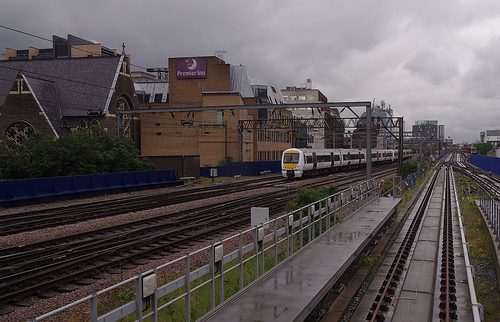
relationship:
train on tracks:
[275, 143, 416, 183] [3, 152, 398, 321]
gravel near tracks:
[2, 172, 278, 251] [3, 152, 398, 321]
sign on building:
[173, 56, 210, 81] [137, 56, 309, 179]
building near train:
[137, 56, 309, 179] [275, 143, 416, 183]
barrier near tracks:
[3, 166, 180, 204] [3, 152, 398, 321]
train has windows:
[275, 143, 416, 183] [304, 153, 341, 164]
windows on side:
[304, 153, 341, 164] [300, 149, 393, 175]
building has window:
[0, 50, 131, 156] [3, 120, 39, 161]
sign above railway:
[173, 56, 210, 81] [3, 152, 398, 321]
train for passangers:
[275, 143, 416, 183] [279, 147, 410, 180]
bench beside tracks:
[183, 194, 405, 321] [3, 152, 398, 321]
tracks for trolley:
[361, 150, 495, 316] [454, 143, 478, 159]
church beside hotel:
[0, 50, 131, 156] [137, 56, 309, 179]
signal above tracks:
[114, 107, 406, 183] [3, 152, 398, 321]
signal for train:
[114, 107, 406, 183] [275, 143, 416, 183]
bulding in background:
[137, 56, 309, 179] [2, 2, 499, 167]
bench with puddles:
[183, 194, 405, 321] [326, 208, 388, 249]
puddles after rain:
[326, 208, 388, 249] [4, 5, 498, 151]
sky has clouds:
[3, 2, 499, 130] [298, 7, 490, 102]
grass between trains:
[85, 214, 309, 314] [280, 135, 489, 182]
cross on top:
[119, 39, 130, 57] [3, 53, 137, 65]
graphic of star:
[173, 56, 210, 81] [182, 56, 193, 66]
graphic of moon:
[173, 56, 210, 81] [187, 58, 200, 70]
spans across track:
[114, 107, 406, 183] [3, 152, 398, 321]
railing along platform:
[49, 174, 383, 321] [183, 194, 405, 321]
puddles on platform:
[326, 208, 388, 249] [183, 194, 405, 321]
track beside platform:
[361, 150, 495, 316] [183, 194, 405, 321]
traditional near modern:
[3, 152, 398, 321] [361, 150, 495, 316]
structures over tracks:
[114, 107, 406, 183] [3, 152, 398, 321]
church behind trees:
[0, 50, 131, 156] [0, 130, 140, 177]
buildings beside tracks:
[2, 45, 445, 162] [3, 152, 398, 321]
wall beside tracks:
[3, 158, 282, 206] [3, 152, 398, 321]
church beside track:
[0, 50, 131, 156] [3, 152, 398, 321]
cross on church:
[119, 39, 130, 57] [0, 50, 131, 156]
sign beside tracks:
[207, 166, 221, 184] [3, 152, 398, 321]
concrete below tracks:
[361, 150, 495, 316] [360, 151, 462, 322]